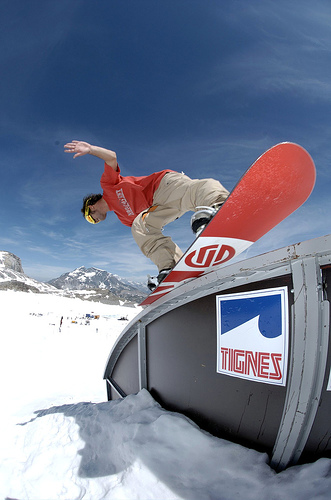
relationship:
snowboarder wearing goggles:
[63, 139, 232, 290] [85, 192, 95, 224]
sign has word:
[214, 287, 295, 390] [221, 346, 286, 380]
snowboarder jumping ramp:
[63, 139, 232, 290] [103, 234, 330, 472]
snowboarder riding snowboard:
[63, 139, 232, 290] [137, 141, 317, 309]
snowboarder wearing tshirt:
[63, 139, 232, 290] [101, 163, 173, 229]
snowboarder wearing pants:
[63, 139, 232, 290] [129, 169, 231, 274]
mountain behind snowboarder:
[47, 264, 154, 307] [63, 139, 232, 290]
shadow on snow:
[17, 386, 328, 499] [3, 287, 329, 498]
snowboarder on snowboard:
[63, 139, 232, 290] [137, 141, 317, 309]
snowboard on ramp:
[137, 141, 317, 309] [103, 234, 330, 472]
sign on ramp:
[214, 287, 295, 390] [103, 234, 330, 472]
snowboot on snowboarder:
[188, 199, 229, 235] [63, 139, 232, 290]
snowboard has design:
[137, 141, 317, 309] [145, 236, 255, 298]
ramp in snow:
[103, 234, 330, 472] [3, 287, 329, 498]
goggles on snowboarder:
[85, 192, 95, 224] [63, 139, 232, 290]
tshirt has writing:
[101, 163, 173, 229] [115, 185, 136, 218]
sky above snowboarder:
[1, 0, 330, 289] [63, 139, 232, 290]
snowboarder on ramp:
[63, 139, 232, 290] [103, 234, 330, 472]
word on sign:
[221, 346, 286, 380] [214, 287, 295, 390]